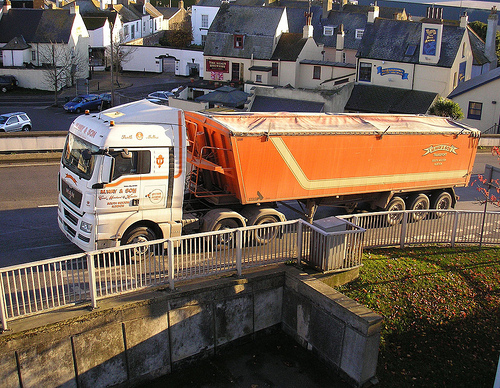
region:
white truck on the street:
[44, 74, 461, 260]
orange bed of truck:
[207, 100, 486, 223]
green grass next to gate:
[409, 243, 487, 316]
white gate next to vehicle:
[66, 233, 153, 302]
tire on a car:
[212, 213, 241, 244]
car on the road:
[1, 105, 49, 140]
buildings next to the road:
[1, 6, 414, 101]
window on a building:
[226, 24, 254, 52]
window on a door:
[102, 134, 158, 194]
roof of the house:
[24, 4, 64, 37]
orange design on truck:
[256, 120, 378, 215]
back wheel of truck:
[435, 192, 473, 234]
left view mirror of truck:
[102, 140, 137, 182]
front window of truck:
[37, 125, 110, 182]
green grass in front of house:
[385, 267, 467, 354]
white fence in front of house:
[18, 243, 123, 303]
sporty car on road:
[60, 85, 110, 118]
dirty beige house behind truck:
[367, 30, 469, 95]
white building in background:
[111, 39, 206, 99]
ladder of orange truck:
[177, 127, 204, 189]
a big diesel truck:
[59, 100, 481, 261]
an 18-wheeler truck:
[54, 94, 482, 261]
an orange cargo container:
[184, 108, 481, 204]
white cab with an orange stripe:
[59, 98, 189, 253]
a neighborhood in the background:
[1, 0, 498, 134]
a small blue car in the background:
[61, 93, 106, 113]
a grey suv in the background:
[0, 111, 35, 129]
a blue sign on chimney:
[424, 25, 437, 56]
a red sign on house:
[206, 58, 228, 73]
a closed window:
[467, 100, 484, 119]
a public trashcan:
[315, 213, 348, 273]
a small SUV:
[0, 110, 35, 134]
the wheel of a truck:
[212, 221, 245, 248]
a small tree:
[467, 145, 498, 249]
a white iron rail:
[239, 217, 317, 274]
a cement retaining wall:
[168, 300, 218, 360]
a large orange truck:
[52, 96, 482, 256]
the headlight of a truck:
[76, 222, 93, 234]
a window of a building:
[234, 35, 244, 49]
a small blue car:
[59, 91, 105, 114]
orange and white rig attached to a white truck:
[184, 107, 480, 205]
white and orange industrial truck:
[57, 95, 187, 262]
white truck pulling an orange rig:
[55, 97, 481, 262]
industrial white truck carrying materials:
[55, 97, 480, 262]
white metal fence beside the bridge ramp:
[88, 209, 498, 309]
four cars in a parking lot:
[0, 74, 175, 131]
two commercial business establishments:
[200, 0, 470, 100]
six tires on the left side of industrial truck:
[120, 190, 450, 260]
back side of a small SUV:
[0, 74, 20, 91]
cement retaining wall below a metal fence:
[0, 262, 387, 386]